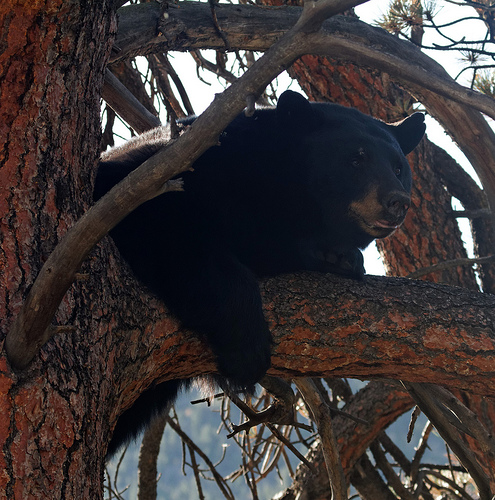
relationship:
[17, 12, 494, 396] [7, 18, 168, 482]
branches on tree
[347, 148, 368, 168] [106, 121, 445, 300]
eye on bear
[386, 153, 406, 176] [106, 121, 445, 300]
eye on bear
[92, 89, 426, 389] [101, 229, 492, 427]
bear on branch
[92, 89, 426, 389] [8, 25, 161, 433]
bear in tree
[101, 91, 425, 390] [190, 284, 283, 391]
bear has paw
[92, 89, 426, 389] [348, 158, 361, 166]
bear has eye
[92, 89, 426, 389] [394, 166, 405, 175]
bear has eye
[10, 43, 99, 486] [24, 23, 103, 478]
tree has sticks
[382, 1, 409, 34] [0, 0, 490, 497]
pine needles are on tree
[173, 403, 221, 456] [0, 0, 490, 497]
white clouds are seen through tree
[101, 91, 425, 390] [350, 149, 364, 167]
bear has eye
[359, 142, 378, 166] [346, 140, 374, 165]
mark above eye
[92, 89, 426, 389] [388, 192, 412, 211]
bear has nostrils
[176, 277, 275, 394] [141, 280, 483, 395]
paw on branch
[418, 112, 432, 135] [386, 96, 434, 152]
tear in ear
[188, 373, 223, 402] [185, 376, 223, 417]
fur reflecting in light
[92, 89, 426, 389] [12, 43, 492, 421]
bear on top of tree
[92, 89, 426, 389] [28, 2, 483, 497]
bear between branches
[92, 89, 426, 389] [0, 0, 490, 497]
bear in tree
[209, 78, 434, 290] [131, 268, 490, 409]
animal on branch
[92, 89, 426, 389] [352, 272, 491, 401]
bear on branch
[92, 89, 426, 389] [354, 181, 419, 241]
bear has mouth